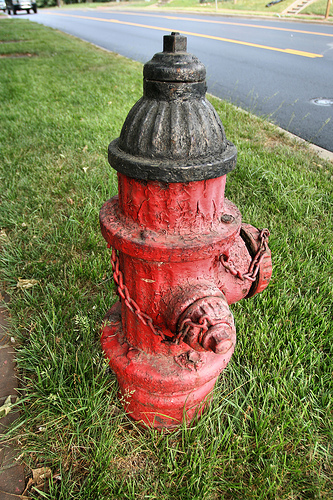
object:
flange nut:
[201, 319, 236, 359]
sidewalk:
[119, 1, 320, 18]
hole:
[0, 43, 38, 64]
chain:
[109, 246, 208, 350]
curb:
[258, 109, 299, 162]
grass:
[0, 18, 331, 498]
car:
[2, 0, 41, 20]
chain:
[216, 230, 271, 294]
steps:
[282, 8, 302, 15]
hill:
[103, 0, 329, 23]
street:
[12, 8, 333, 149]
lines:
[50, 12, 324, 64]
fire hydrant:
[93, 20, 273, 437]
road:
[4, 6, 331, 149]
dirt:
[0, 292, 32, 499]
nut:
[160, 27, 189, 54]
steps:
[289, 1, 307, 10]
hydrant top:
[103, 18, 242, 188]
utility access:
[306, 89, 333, 114]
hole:
[0, 33, 24, 45]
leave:
[12, 271, 38, 296]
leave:
[1, 385, 20, 416]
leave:
[19, 456, 57, 500]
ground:
[1, 0, 333, 497]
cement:
[0, 314, 56, 499]